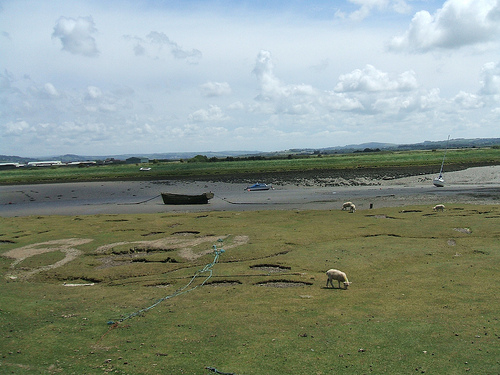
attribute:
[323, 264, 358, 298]
sheep — small, viewable, white, eating, tiny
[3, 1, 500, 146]
sky — bright, massive, white, blue, cloudy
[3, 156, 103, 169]
buildings — far, flat, white